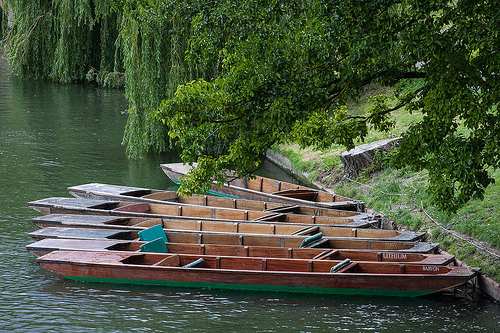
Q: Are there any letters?
A: Yes, there are letters.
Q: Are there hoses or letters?
A: Yes, there are letters.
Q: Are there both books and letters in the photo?
A: No, there are letters but no books.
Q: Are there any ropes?
A: No, there are no ropes.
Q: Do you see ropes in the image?
A: No, there are no ropes.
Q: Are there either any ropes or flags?
A: No, there are no ropes or flags.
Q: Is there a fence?
A: No, there are no fences.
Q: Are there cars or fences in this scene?
A: No, there are no fences or cars.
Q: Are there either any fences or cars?
A: No, there are no fences or cars.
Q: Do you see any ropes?
A: No, there are no ropes.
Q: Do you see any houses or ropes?
A: No, there are no ropes or houses.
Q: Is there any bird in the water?
A: No, there are boats in the water.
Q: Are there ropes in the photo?
A: No, there are no ropes.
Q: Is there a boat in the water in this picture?
A: Yes, there are boats in the water.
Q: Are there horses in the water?
A: No, there are boats in the water.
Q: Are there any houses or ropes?
A: No, there are no houses or ropes.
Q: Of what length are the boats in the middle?
A: The boats are long.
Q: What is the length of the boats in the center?
A: The boats are long.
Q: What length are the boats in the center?
A: The boats are long.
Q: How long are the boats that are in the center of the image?
A: The boats are long.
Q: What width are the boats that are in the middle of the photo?
A: The boats are narrow.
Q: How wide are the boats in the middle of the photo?
A: The boats are narrow.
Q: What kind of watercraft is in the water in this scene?
A: The watercraft is boats.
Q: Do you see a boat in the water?
A: Yes, there are boats in the water.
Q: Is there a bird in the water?
A: No, there are boats in the water.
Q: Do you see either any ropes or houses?
A: No, there are no houses or ropes.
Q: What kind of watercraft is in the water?
A: The watercraft is boats.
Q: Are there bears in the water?
A: No, there are boats in the water.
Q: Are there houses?
A: No, there are no houses.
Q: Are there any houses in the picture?
A: No, there are no houses.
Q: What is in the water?
A: The boats are in the water.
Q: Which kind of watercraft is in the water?
A: The watercraft is boats.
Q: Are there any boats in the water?
A: Yes, there are boats in the water.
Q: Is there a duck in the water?
A: No, there are boats in the water.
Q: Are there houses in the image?
A: No, there are no houses.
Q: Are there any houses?
A: No, there are no houses.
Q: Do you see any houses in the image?
A: No, there are no houses.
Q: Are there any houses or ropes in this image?
A: No, there are no houses or ropes.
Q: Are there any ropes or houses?
A: No, there are no houses or ropes.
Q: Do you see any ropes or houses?
A: No, there are no houses or ropes.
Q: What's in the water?
A: The boats are in the water.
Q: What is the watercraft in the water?
A: The watercraft is boats.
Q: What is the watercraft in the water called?
A: The watercraft is boats.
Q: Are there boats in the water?
A: Yes, there are boats in the water.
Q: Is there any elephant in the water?
A: No, there are boats in the water.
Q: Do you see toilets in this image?
A: No, there are no toilets.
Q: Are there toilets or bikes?
A: No, there are no toilets or bikes.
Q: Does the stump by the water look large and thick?
A: Yes, the stump is large and thick.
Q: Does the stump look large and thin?
A: No, the stump is large but thick.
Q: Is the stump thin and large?
A: No, the stump is large but thick.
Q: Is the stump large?
A: Yes, the stump is large.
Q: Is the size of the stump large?
A: Yes, the stump is large.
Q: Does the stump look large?
A: Yes, the stump is large.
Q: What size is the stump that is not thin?
A: The stump is large.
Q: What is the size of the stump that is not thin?
A: The stump is large.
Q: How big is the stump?
A: The stump is large.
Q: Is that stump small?
A: No, the stump is large.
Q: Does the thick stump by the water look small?
A: No, the stump is large.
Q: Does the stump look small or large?
A: The stump is large.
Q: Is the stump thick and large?
A: Yes, the stump is thick and large.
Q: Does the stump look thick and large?
A: Yes, the stump is thick and large.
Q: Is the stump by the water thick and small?
A: No, the stump is thick but large.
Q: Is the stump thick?
A: Yes, the stump is thick.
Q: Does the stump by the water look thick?
A: Yes, the stump is thick.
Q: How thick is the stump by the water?
A: The stump is thick.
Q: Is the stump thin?
A: No, the stump is thick.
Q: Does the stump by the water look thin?
A: No, the stump is thick.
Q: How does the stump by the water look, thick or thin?
A: The stump is thick.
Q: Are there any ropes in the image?
A: No, there are no ropes.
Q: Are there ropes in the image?
A: No, there are no ropes.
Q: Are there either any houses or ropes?
A: No, there are no ropes or houses.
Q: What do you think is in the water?
A: The boats are in the water.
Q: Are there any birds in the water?
A: No, there are boats in the water.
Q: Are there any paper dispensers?
A: No, there are no paper dispensers.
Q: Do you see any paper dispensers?
A: No, there are no paper dispensers.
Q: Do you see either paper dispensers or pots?
A: No, there are no paper dispensers or pots.